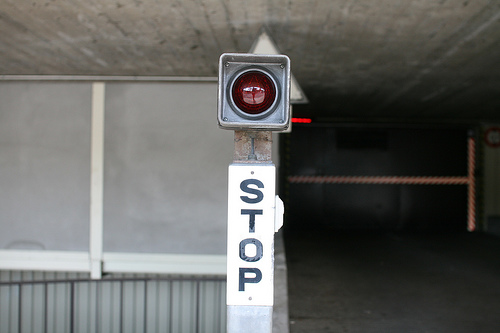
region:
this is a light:
[205, 30, 312, 143]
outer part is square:
[200, 39, 320, 154]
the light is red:
[225, 62, 285, 138]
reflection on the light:
[232, 67, 282, 118]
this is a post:
[210, 147, 284, 331]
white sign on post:
[218, 135, 292, 330]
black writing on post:
[220, 138, 282, 318]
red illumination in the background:
[285, 102, 321, 147]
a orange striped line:
[279, 161, 476, 206]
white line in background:
[60, 76, 134, 312]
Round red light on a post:
[231, 70, 278, 114]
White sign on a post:
[225, 166, 272, 305]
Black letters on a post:
[238, 174, 268, 295]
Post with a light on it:
[214, 54, 284, 332]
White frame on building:
[2, 252, 225, 279]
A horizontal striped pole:
[284, 173, 465, 184]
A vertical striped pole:
[463, 137, 478, 234]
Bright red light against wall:
[291, 114, 312, 123]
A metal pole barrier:
[293, 140, 479, 230]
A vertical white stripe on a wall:
[87, 83, 111, 278]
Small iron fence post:
[13, 279, 21, 330]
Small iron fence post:
[35, 281, 60, 332]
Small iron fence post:
[59, 278, 84, 320]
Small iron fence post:
[111, 272, 134, 332]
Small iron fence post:
[138, 274, 155, 332]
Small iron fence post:
[162, 274, 186, 323]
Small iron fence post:
[181, 265, 213, 327]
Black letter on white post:
[232, 179, 268, 205]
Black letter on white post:
[236, 207, 267, 237]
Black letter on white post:
[230, 236, 264, 264]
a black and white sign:
[229, 165, 271, 299]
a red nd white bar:
[293, 176, 468, 188]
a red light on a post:
[219, 53, 287, 124]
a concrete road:
[312, 245, 485, 328]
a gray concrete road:
[308, 239, 489, 319]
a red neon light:
[290, 116, 311, 126]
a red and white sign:
[486, 126, 496, 146]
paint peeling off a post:
[271, 170, 281, 295]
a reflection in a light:
[231, 70, 272, 107]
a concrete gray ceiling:
[347, 0, 489, 109]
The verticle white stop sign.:
[223, 159, 270, 304]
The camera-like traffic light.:
[210, 41, 299, 134]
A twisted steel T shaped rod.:
[286, 135, 497, 232]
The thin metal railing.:
[0, 277, 224, 331]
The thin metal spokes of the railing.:
[68, 279, 76, 331]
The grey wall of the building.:
[134, 99, 200, 252]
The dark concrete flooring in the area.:
[293, 236, 497, 331]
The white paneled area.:
[0, 76, 227, 269]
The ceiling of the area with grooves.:
[7, 34, 196, 73]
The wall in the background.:
[301, 187, 446, 224]